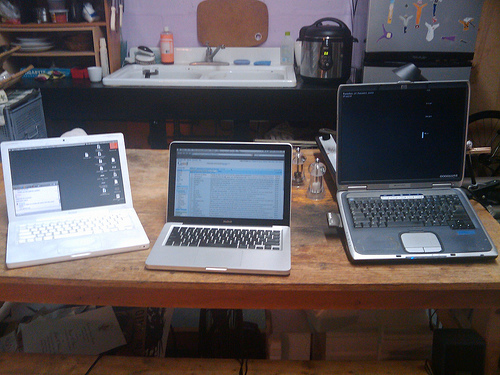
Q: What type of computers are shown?
A: Laptops.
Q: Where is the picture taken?
A: A workroom.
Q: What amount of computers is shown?
A: Three.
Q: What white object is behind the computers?
A: A sink.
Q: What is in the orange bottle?
A: Soap.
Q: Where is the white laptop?
A: The far left.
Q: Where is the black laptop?
A: The far right.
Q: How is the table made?
A: Of wood.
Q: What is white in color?
A: Sink.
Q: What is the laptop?
A: White.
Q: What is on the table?
A: Laptop.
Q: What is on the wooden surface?
A: Laptops.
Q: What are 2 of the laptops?
A: On.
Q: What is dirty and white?
A: Sink.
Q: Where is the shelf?
A: Near sink.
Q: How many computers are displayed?
A: Three.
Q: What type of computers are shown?
A: Laptops.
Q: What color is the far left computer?
A: White.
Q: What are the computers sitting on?
A: A desk.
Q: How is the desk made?
A: Of wood.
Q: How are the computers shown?
A: Open.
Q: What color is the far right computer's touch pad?
A: Silver.